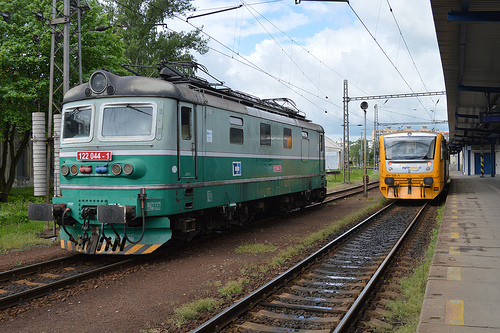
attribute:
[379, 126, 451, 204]
train — yellow, stopped, orange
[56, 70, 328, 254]
train — green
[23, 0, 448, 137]
clouds — blue, white, big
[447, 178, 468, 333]
lines — dotted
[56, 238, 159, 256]
stripes — black, orange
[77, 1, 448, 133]
sky — blue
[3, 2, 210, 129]
leaves — green